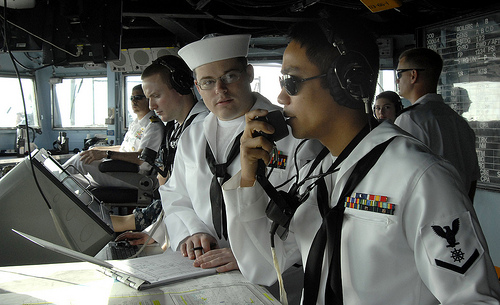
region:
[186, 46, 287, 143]
a man wearing glasses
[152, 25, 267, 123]
a man wearing a white hat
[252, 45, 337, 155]
a man wearing black sunglasses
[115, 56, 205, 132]
a man wearing headphones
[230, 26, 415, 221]
a man talking on a walkie talkie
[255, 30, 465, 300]
a man wearing a white shirt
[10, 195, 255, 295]
a silver laptop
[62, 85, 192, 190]
a man wearing a watch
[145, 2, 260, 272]
a man holding a pen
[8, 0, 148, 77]
a black screen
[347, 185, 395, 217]
navy strips on girls uniform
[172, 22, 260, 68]
navy hat on man's head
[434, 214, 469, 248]
navy eagle logo on uniform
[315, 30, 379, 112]
headset on man's head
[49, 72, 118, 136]
window in navy ship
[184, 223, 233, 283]
navy man's pair of hands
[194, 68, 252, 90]
glasses on sailor's face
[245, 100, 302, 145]
mic to speak into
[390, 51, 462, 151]
sailor in the background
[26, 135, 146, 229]
navy controls in the ship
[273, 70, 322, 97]
Person wearing dark sunglasses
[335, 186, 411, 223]
A multicolored badge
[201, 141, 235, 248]
A blue marine tie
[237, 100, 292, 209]
A hand holding a speaker phone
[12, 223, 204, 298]
An open clip board on the desk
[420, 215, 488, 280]
A symbol on the sleeve of a shirt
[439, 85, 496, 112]
Reflection of someones face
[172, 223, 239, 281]
Hands on a clipboard, holding a pen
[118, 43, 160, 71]
A set of speakers overhead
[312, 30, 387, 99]
A person wearing headphones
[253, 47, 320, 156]
sailor is wearing sunglasses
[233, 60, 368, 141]
sailor is wearing sunglasses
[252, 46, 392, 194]
sailor is wearing sunglasses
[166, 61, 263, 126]
man is wearing eyeglasses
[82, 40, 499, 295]
men on a boat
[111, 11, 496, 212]
people on a boat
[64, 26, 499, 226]
men in sailor uniforms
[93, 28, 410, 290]
sailors on a boat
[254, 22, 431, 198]
a men wearing sunglasses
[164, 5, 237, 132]
a man wearing glassses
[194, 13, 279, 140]
a man with a white hat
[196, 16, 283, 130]
a man with a white sailor hat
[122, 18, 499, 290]
men with ties around their neck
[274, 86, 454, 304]
men with mens on their uniform